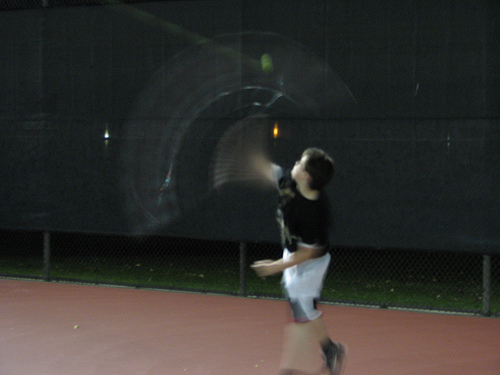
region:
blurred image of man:
[250, 52, 345, 374]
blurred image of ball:
[252, 42, 280, 79]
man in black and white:
[241, 124, 351, 373]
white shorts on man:
[268, 243, 340, 330]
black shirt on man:
[269, 168, 338, 253]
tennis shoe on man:
[323, 337, 350, 369]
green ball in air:
[254, 49, 279, 77]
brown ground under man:
[0, 270, 490, 373]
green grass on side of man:
[24, 234, 497, 317]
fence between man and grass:
[4, 224, 496, 316]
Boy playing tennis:
[196, 78, 382, 373]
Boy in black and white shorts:
[268, 233, 343, 335]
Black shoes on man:
[306, 330, 349, 371]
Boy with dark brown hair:
[287, 138, 339, 210]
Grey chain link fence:
[8, 213, 496, 328]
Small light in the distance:
[262, 116, 287, 148]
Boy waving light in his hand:
[93, 26, 348, 219]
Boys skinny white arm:
[222, 236, 325, 293]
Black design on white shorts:
[305, 290, 327, 322]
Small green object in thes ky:
[252, 49, 289, 76]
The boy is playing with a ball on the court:
[241, 133, 385, 367]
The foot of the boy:
[316, 335, 357, 372]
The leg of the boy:
[301, 308, 338, 344]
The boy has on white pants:
[272, 241, 337, 328]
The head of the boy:
[286, 140, 338, 198]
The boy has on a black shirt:
[264, 174, 335, 259]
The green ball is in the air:
[251, 53, 280, 72]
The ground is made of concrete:
[11, 284, 220, 374]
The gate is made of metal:
[346, 155, 468, 300]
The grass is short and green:
[54, 250, 240, 282]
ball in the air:
[251, 60, 276, 82]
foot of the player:
[306, 330, 346, 365]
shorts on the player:
[261, 243, 328, 329]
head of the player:
[281, 150, 336, 197]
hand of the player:
[233, 260, 281, 285]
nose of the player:
[289, 160, 296, 172]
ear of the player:
[296, 168, 311, 184]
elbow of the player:
[286, 248, 333, 263]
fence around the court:
[381, 276, 400, 298]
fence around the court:
[188, 270, 208, 284]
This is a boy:
[202, 108, 386, 357]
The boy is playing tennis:
[127, 38, 399, 363]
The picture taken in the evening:
[13, 32, 493, 351]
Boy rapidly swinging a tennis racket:
[100, 50, 369, 238]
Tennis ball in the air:
[246, 47, 278, 84]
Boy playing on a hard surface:
[15, 289, 467, 374]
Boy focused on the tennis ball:
[280, 141, 332, 201]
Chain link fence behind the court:
[26, 221, 250, 289]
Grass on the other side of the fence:
[344, 267, 472, 305]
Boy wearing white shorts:
[267, 237, 335, 323]